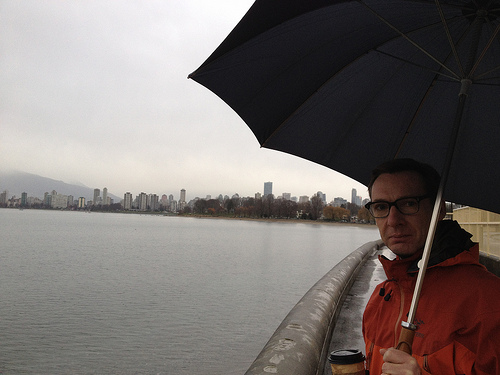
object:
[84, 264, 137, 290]
water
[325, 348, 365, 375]
cup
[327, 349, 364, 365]
lid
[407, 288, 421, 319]
pole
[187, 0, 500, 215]
umbrella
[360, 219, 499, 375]
coat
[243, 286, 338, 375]
railing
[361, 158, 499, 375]
man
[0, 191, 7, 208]
buildings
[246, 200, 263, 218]
trees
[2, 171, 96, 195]
mountain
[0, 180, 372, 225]
city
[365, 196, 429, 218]
glasses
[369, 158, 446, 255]
head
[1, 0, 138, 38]
sky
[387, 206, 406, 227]
nose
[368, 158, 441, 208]
hair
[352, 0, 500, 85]
spokes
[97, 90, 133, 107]
clouds